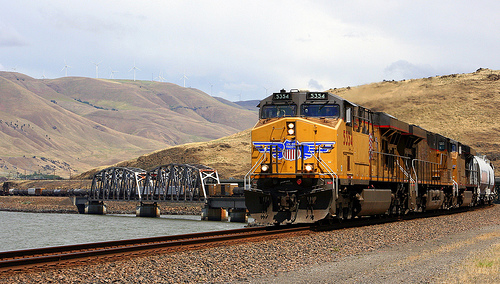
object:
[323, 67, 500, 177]
mountain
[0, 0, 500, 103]
skies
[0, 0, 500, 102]
cloudy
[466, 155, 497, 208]
water tank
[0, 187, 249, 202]
train track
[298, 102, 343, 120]
windows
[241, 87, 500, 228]
train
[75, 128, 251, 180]
hillside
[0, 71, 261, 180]
hills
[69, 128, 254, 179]
mountain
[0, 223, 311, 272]
tracks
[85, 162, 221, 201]
metal bridge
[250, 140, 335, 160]
paint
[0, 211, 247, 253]
water